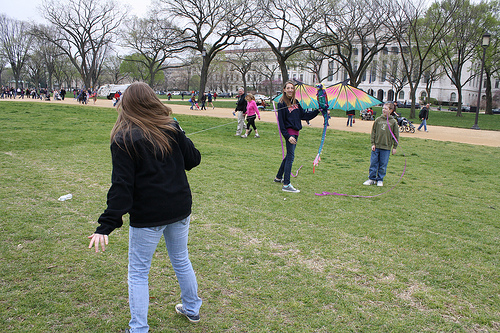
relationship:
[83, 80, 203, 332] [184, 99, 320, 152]
girl holding kite string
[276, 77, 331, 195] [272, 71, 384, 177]
girl holding kite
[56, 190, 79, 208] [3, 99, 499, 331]
bottle on grass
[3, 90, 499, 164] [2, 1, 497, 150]
walking path in background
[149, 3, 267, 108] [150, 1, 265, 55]
tree has no leaves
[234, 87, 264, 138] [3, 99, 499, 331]
people are walking on grass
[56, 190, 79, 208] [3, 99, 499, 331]
litter on grass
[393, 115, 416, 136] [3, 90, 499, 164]
stroller on walking path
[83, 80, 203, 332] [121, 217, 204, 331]
girl wearing jeans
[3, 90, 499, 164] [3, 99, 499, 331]
walking path near grass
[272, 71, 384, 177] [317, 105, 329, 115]
kite in girl's hadn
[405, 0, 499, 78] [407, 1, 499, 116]
leaves are on tree